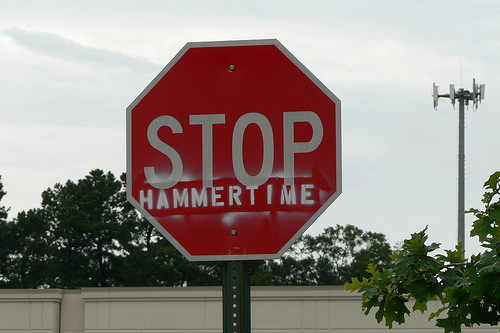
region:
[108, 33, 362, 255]
stop sign with writing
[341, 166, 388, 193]
white clouds in blue sky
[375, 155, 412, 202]
white clouds in blue sky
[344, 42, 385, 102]
white clouds in blue sky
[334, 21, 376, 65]
white clouds in blue sky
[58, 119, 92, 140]
white clouds in blue sky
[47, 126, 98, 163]
white clouds in blue sky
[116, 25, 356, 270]
the STOP sign on pole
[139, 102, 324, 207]
STOP sign is white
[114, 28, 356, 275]
border of sign is white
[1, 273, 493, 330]
a fence color white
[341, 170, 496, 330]
a plant with green leaves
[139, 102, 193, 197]
letter S on sign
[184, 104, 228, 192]
letter T on sign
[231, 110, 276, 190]
letter O on sign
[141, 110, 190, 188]
white letter on sign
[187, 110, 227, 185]
white letter on sign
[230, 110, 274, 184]
white letter on sign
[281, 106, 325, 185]
white letter on sign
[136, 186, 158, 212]
white letter on sign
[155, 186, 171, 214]
white letter on sign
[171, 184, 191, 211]
white letter on sign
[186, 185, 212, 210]
white letter on sign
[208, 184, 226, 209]
white letter on sign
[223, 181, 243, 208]
white letter on sign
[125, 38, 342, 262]
the sign shaped like an octagon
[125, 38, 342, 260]
the red and white STOP sign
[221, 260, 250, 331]
the pole for the sign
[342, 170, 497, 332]
the tree closest to the sign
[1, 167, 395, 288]
the trees behind the sign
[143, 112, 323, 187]
the word STOP on the sign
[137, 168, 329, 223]
the white spray paint on the sign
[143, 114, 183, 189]
the letter "S" on the sign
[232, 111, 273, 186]
the letter "O" on the sign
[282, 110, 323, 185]
the letter "P" on the sign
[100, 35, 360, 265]
stop sign with graffiti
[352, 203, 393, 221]
white clouds in blue sky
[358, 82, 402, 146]
white clouds in blue sky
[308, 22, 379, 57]
white clouds in blue sky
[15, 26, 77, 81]
white clouds in blue sky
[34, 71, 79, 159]
white clouds in blue sky